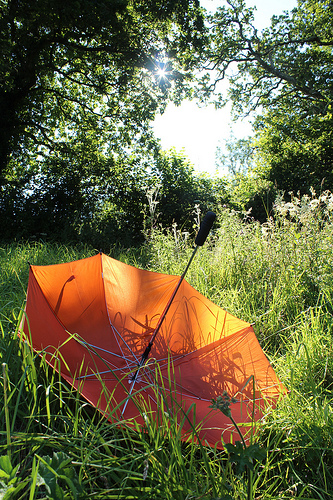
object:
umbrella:
[16, 210, 289, 454]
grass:
[0, 324, 294, 500]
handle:
[194, 210, 216, 247]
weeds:
[140, 183, 202, 274]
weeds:
[258, 176, 333, 311]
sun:
[156, 68, 167, 81]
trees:
[215, 131, 253, 214]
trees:
[201, 0, 332, 120]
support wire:
[111, 323, 140, 365]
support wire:
[141, 354, 184, 367]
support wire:
[120, 367, 141, 418]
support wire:
[77, 365, 139, 380]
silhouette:
[112, 295, 284, 404]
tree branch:
[262, 87, 301, 109]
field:
[0, 240, 331, 497]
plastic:
[142, 341, 153, 359]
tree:
[48, 112, 107, 247]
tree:
[86, 182, 152, 252]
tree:
[152, 149, 218, 245]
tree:
[234, 164, 275, 223]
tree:
[253, 104, 333, 201]